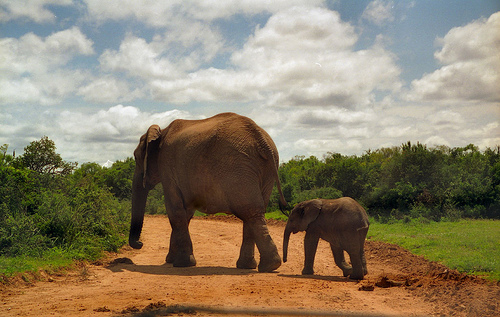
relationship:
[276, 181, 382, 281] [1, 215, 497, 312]
baby elephant walking on road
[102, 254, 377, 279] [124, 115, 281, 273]
shadows cast of elephants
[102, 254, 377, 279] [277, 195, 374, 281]
shadows cast of elephants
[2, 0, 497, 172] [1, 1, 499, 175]
clouds in sky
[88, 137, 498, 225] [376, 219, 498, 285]
tree line behind grassy field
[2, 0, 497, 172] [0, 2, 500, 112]
clouds in blue sky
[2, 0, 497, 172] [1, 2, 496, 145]
clouds in sky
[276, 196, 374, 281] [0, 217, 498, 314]
baby elephant walking along trail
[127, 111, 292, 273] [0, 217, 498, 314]
elephant walking along trail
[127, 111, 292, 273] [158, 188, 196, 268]
elephant with leg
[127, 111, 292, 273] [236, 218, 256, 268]
elephant with leg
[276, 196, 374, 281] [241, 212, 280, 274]
baby elephant with leg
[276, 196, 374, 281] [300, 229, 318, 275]
baby elephant with leg